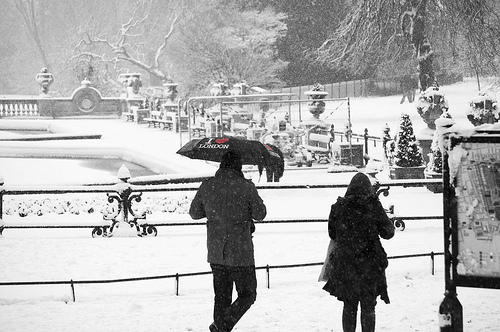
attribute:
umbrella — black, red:
[175, 134, 286, 181]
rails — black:
[0, 181, 450, 304]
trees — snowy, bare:
[14, 3, 499, 98]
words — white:
[197, 134, 230, 153]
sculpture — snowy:
[36, 68, 454, 178]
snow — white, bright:
[1, 4, 489, 327]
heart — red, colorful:
[213, 136, 230, 148]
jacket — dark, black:
[326, 195, 392, 292]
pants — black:
[329, 261, 374, 332]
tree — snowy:
[319, 1, 482, 87]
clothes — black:
[202, 174, 260, 275]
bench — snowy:
[134, 106, 176, 129]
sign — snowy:
[429, 109, 498, 326]